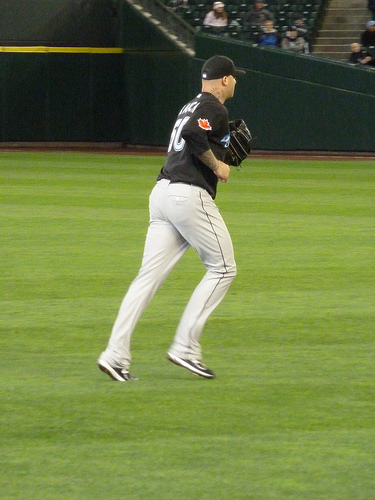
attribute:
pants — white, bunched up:
[101, 180, 243, 372]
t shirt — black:
[156, 90, 229, 199]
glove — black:
[228, 116, 255, 166]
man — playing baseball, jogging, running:
[96, 51, 253, 383]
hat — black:
[196, 50, 247, 84]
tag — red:
[195, 116, 218, 134]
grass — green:
[1, 148, 374, 500]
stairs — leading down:
[133, 0, 197, 55]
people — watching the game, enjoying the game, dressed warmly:
[202, 1, 374, 64]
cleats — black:
[96, 346, 216, 388]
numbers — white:
[166, 115, 189, 155]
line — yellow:
[1, 45, 125, 57]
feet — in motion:
[96, 351, 218, 385]